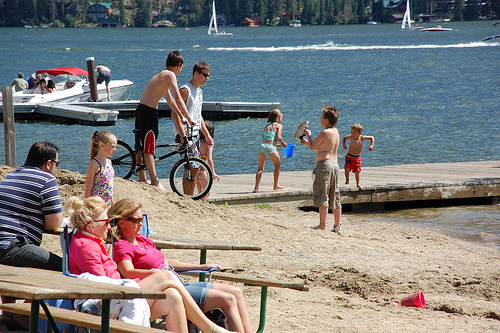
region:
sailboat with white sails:
[192, 1, 238, 37]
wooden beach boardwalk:
[370, 165, 495, 205]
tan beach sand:
[293, 241, 497, 283]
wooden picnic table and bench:
[2, 272, 152, 327]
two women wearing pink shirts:
[50, 187, 197, 291]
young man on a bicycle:
[113, 51, 207, 201]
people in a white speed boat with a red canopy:
[1, 35, 133, 99]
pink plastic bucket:
[381, 289, 438, 317]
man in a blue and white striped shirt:
[0, 127, 64, 269]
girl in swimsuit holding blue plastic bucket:
[250, 103, 297, 194]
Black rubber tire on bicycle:
[171, 153, 212, 198]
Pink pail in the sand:
[400, 288, 427, 310]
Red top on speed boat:
[36, 64, 89, 76]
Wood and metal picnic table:
[8, 273, 164, 324]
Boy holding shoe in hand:
[296, 107, 343, 236]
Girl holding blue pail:
[248, 109, 291, 197]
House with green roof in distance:
[82, 1, 114, 25]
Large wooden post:
[0, 81, 17, 164]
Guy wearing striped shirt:
[2, 141, 65, 265]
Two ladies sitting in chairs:
[72, 202, 191, 331]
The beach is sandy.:
[0, 163, 499, 330]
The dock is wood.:
[127, 152, 499, 209]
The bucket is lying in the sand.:
[388, 271, 448, 309]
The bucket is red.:
[393, 280, 439, 315]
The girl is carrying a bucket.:
[242, 98, 301, 210]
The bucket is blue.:
[283, 138, 305, 164]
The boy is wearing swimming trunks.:
[336, 116, 383, 188]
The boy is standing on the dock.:
[340, 125, 375, 205]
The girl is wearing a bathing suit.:
[248, 105, 298, 208]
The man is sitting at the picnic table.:
[2, 138, 320, 330]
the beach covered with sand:
[301, 240, 400, 303]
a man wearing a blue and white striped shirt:
[0, 129, 67, 269]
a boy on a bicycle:
[96, 35, 211, 212]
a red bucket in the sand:
[387, 275, 442, 322]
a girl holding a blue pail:
[238, 104, 298, 201]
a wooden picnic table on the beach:
[1, 255, 172, 332]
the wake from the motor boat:
[263, 32, 498, 67]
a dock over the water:
[389, 130, 498, 210]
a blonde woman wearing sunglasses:
[107, 201, 155, 243]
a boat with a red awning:
[2, 47, 126, 126]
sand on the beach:
[313, 246, 403, 271]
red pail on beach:
[393, 286, 438, 318]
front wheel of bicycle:
[175, 156, 215, 203]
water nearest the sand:
[437, 207, 487, 242]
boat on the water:
[207, 2, 234, 50]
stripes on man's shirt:
[11, 181, 32, 208]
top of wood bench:
[12, 262, 48, 284]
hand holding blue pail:
[280, 140, 298, 166]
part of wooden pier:
[390, 162, 453, 181]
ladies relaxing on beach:
[59, 187, 241, 331]